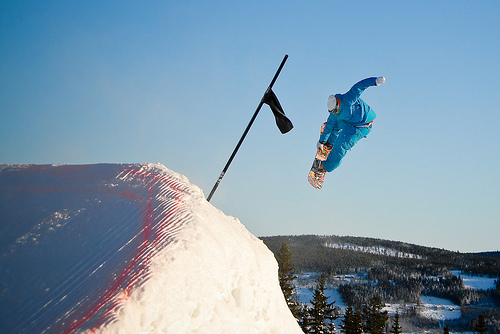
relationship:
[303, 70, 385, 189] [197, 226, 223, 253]
man has on a snow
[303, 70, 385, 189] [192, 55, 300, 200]
man falls of h skiis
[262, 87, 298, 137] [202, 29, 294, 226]
flag on pole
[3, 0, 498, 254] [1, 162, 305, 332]
blue sky above snow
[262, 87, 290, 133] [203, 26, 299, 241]
flag on pole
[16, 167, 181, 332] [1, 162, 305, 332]
paint on snow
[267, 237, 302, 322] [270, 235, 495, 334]
tree on mountainside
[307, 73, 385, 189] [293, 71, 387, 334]
snowboarder doing a trick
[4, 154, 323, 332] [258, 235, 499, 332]
field with trees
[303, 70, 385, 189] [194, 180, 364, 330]
man falls off cliff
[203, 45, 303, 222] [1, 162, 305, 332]
pole in snow